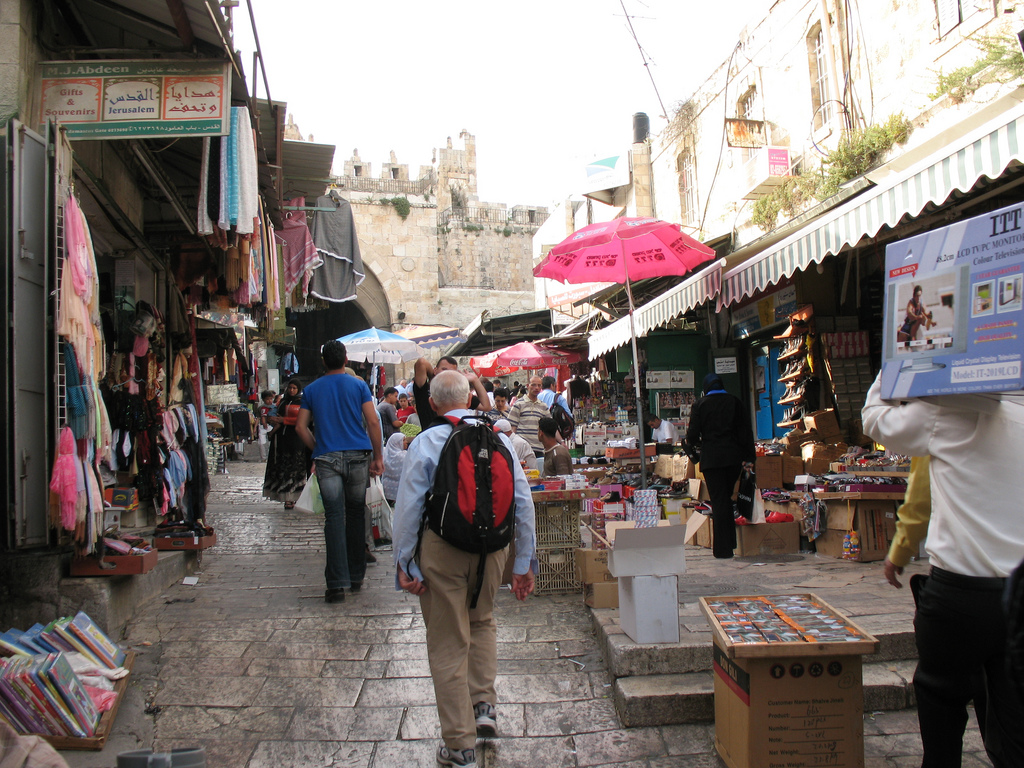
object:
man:
[391, 366, 541, 767]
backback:
[424, 414, 519, 553]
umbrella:
[532, 217, 716, 286]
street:
[54, 448, 993, 768]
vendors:
[2, 125, 1023, 768]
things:
[0, 64, 1022, 768]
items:
[0, 610, 132, 768]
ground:
[55, 455, 1024, 763]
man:
[295, 339, 386, 604]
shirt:
[298, 372, 374, 461]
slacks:
[414, 528, 509, 755]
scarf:
[47, 427, 82, 537]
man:
[859, 375, 1021, 766]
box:
[881, 201, 1024, 399]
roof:
[39, 0, 335, 308]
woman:
[262, 378, 314, 510]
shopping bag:
[361, 471, 396, 551]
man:
[506, 375, 553, 479]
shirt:
[507, 393, 553, 452]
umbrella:
[321, 326, 430, 364]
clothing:
[95, 297, 226, 556]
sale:
[87, 219, 323, 556]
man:
[644, 414, 679, 449]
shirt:
[649, 419, 681, 447]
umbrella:
[468, 338, 583, 378]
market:
[0, 0, 1024, 768]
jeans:
[314, 451, 372, 595]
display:
[0, 181, 365, 572]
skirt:
[262, 414, 317, 505]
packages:
[605, 509, 709, 643]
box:
[701, 591, 884, 767]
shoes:
[770, 302, 846, 541]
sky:
[180, 0, 761, 214]